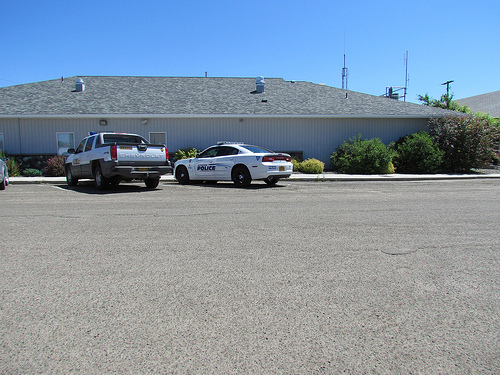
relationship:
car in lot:
[174, 143, 293, 192] [130, 212, 428, 318]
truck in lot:
[51, 125, 180, 200] [130, 212, 428, 318]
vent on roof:
[64, 77, 96, 96] [133, 76, 157, 98]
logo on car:
[186, 161, 226, 178] [174, 143, 293, 192]